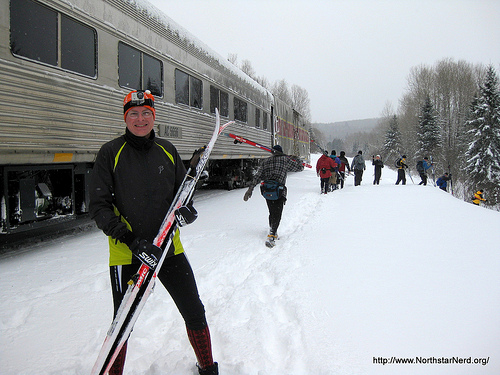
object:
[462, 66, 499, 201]
pine tree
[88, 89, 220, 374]
skiier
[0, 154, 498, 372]
trail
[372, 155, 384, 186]
skiier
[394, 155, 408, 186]
skiier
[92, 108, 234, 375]
skis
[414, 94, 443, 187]
tree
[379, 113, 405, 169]
tree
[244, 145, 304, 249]
man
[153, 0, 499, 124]
clouds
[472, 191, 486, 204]
yellow jacket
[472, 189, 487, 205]
man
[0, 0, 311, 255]
train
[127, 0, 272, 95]
snow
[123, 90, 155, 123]
orange hat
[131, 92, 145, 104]
camera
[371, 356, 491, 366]
address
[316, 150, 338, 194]
person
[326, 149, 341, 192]
person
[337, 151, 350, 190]
person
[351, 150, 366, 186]
person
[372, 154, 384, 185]
person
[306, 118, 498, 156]
hill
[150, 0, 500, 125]
clouds sky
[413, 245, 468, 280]
white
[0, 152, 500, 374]
path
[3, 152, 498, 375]
snow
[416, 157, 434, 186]
person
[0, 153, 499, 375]
ground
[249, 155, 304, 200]
shirt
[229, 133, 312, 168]
skiis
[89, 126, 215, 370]
attire